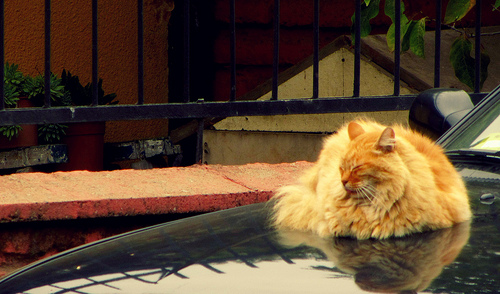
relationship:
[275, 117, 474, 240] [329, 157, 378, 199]
cat has face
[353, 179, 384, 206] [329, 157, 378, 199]
whiskers on face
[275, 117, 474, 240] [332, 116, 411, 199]
cat has head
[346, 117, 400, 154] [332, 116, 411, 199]
ears on head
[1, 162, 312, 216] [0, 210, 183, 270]
top of wall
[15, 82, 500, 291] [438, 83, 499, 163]
car has windshield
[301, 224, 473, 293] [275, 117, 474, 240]
reflection of cat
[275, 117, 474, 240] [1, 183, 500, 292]
cat on hood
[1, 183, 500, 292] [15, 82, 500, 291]
hood of car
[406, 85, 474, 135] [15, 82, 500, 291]
mirror on car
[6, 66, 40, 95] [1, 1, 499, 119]
leaves behind railing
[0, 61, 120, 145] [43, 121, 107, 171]
leaves in pot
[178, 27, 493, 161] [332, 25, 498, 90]
shed with roof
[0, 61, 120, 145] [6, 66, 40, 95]
leaves with leaves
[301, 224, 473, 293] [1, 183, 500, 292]
reflection in hood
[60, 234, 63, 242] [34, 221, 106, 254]
line on brick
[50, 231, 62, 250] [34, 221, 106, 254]
crack in brick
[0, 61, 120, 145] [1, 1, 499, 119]
leaves behind railing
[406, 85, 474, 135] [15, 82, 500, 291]
mirror of car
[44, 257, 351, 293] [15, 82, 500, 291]
reflection on car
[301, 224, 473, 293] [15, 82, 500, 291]
reflection on car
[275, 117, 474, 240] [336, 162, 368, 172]
cat with eyes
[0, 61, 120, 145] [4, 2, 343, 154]
leaves next to building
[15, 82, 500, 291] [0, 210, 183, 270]
car next to wall